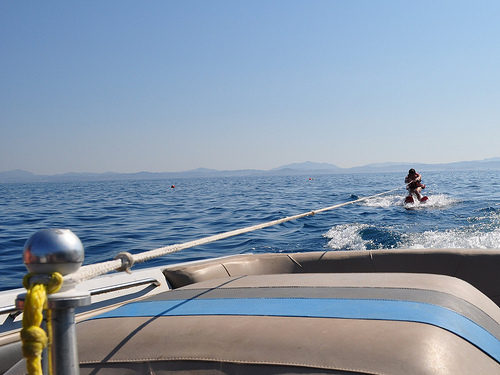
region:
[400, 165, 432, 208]
A person is waterskiing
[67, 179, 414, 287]
Along white rope for waterskiing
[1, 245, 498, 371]
Back of a boat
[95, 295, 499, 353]
Blue strip of leather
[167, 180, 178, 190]
Red water buoy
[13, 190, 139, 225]
Blue Ocean Water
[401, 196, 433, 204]
Water skies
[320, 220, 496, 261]
Small wave from back of boat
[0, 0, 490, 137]
Clear blue sky with no clouds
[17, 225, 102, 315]
A silver boat hitch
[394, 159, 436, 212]
Person surfing in the water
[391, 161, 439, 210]
Person is crouched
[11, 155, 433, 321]
Man holding a rope tied in a boat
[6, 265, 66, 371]
Yellow rope hanging from a pole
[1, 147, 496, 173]
Mountains in the background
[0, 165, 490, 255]
Water is blue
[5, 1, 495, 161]
Sky is blue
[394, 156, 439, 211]
Person has short hair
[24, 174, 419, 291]
Rope is white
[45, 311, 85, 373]
Pole is grey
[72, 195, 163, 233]
blue body on water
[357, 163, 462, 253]
water skier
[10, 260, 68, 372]
yellow marine rope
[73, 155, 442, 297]
white ski pull rope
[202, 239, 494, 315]
back seating on boat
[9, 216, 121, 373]
metal pole on boat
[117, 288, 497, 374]
blue and gray leather covering on boat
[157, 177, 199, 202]
red bowie in water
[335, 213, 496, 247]
water caps behind boat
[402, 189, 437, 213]
red water skis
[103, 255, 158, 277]
the rope is white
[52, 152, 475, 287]
the rope is long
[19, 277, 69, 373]
the rope is tied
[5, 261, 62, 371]
the rope is yellow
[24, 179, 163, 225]
the water is blue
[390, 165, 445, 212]
the person is holding the rope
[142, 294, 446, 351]
the line is blue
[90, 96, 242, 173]
the sky is blue and white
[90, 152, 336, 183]
there are mountains in the horizons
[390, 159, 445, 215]
the person is wearing water board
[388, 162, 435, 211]
Water skier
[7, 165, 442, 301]
Water skier holding a rope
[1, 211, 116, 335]
Rope is tied in a boat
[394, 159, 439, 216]
Skier is bend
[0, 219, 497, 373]
Boat pulling a skier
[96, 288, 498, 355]
Blue stripe on boat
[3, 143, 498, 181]
Mountain in the background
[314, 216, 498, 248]
Choppy water formed by the boat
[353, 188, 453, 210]
Choppy water formed by the skier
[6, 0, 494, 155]
Ski is blue